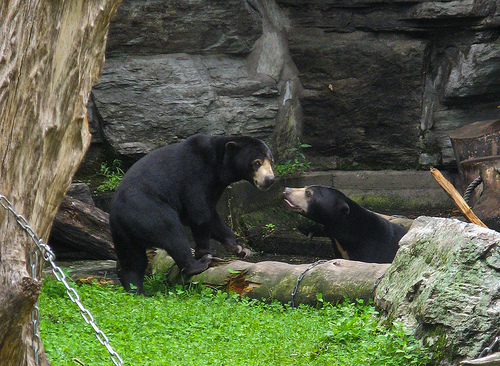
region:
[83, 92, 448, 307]
Two fully grown black bears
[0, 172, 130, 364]
Chain tied around a tree trunk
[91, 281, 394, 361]
Bright green foliage growing on the ground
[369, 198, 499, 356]
Large boulder with green moss growing on it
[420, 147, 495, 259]
Large stick leaning against the boulder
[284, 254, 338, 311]
Chain wrapped around the fallen tree trunk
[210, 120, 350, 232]
Two bears with tan colored noses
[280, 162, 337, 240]
Bear with the mouth open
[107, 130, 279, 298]
Bear standing on a fallen tree trunk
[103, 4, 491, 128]
Large stone and boulder wall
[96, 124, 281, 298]
Black bear crawling over a wooden log.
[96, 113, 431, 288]
Two black bears with their noses close together.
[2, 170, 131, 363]
A chain wrapped around a wooden trunk.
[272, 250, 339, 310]
A piece of chain laying over the top of a log.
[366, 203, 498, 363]
A large boulder with green moss on it's side.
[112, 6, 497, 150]
Large walls made of stone.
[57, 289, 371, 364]
Green leafy growth on the ground.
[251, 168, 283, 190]
Brown and black bear nose.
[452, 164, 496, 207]
Large piece of rope.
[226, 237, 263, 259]
Bear paw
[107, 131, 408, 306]
Two black bears in a zoo.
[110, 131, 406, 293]
Two black bears face to face.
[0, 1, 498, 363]
Black bears with white faces in habitat.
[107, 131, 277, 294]
Black bear with white nose standing.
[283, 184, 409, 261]
Black bear moving towards bear standing.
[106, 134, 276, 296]
Black standing with foot on the ground.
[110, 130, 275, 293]
Black bear with white nose and foot on a log.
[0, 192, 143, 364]
Change attached to a tree.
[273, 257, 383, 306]
Chain around a pole.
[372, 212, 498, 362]
Rock on the ground in bear's habitat.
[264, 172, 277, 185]
the nose of a bear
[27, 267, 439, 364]
green grass on the ground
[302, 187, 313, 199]
the eye of a bear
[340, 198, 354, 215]
the ear of a bear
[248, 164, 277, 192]
the snout of a bear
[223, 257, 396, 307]
a log on the ground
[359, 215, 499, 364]
a large gray rock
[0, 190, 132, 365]
a metal chain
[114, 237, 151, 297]
the leg of a bear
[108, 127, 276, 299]
a black bear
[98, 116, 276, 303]
Black bear in zoo setting.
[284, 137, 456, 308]
Second black bear in zoo setting.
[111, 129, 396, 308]
Two black bears in zoo.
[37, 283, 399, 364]
Grass is green.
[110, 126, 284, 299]
Bear is on log.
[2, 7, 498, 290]
Rocks and logs in background.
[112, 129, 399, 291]
Two bears communicating.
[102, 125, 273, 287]
Bear has brown snout.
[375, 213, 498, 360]
rock has green growth.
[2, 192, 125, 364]
chain around tree.